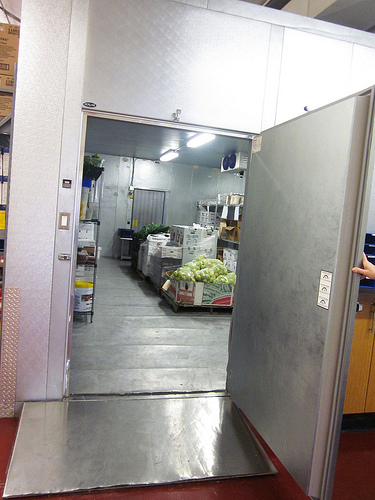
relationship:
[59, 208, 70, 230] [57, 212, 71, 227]
switch color white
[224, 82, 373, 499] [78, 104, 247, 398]
door of a cooler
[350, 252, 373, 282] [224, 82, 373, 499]
hand holding door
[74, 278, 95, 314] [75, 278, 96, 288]
bucket has yellow lid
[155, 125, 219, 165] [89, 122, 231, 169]
lights are on ceiling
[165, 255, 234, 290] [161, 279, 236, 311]
fruit in a box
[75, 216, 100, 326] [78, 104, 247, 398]
shelving in a cooler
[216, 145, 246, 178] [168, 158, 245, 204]
fans are on a wall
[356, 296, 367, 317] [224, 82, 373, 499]
latch for a door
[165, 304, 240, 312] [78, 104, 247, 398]
palette in a cooler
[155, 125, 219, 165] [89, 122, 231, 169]
light on ceiling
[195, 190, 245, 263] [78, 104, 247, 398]
shelving inside cooler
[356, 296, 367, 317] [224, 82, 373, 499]
latch for door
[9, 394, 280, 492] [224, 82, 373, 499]
ramp for door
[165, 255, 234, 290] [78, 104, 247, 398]
food in fridge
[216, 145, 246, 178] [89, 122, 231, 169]
fan on ceiling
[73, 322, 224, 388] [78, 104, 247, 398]
floor of a fridge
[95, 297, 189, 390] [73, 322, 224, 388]
lines are on floor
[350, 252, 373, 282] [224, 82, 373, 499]
hand on door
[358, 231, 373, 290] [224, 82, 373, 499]
cabinet next to door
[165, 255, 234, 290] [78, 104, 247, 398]
apples are on a cooler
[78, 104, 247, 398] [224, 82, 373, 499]
cooler has a door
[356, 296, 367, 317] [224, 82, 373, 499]
handle in door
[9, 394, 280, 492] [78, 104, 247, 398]
board in front of cooler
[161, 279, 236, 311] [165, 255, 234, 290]
box containing apples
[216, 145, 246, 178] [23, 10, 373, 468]
fans on cooling unit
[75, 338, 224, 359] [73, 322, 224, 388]
seam in floor